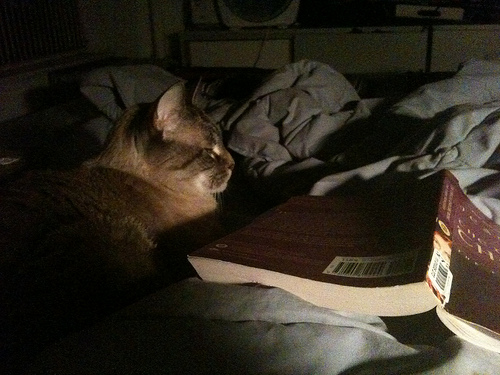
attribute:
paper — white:
[188, 258, 433, 318]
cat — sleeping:
[43, 85, 211, 283]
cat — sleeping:
[35, 87, 229, 311]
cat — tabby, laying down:
[70, 90, 300, 272]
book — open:
[246, 161, 486, 316]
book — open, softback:
[224, 145, 469, 340]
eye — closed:
[191, 126, 240, 171]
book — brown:
[195, 177, 483, 322]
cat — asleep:
[35, 65, 305, 284]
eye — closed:
[201, 131, 229, 162]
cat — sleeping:
[11, 64, 251, 365]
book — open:
[180, 148, 496, 373]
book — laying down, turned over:
[179, 162, 498, 349]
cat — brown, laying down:
[6, 78, 237, 351]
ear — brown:
[154, 79, 189, 137]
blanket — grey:
[234, 42, 496, 162]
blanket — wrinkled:
[233, 31, 494, 171]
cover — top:
[188, 301, 321, 362]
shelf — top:
[162, 21, 436, 65]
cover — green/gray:
[11, 54, 494, 366]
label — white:
[315, 231, 419, 295]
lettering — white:
[277, 212, 331, 245]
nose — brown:
[220, 152, 234, 179]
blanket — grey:
[303, 88, 394, 143]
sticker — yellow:
[421, 211, 462, 245]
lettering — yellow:
[396, 190, 492, 255]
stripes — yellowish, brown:
[62, 166, 162, 230]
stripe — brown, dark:
[170, 138, 228, 189]